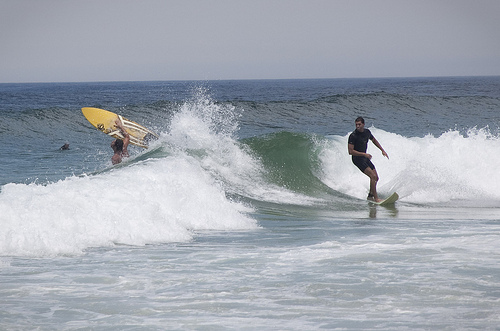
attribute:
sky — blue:
[0, 0, 499, 84]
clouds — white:
[1, 0, 499, 83]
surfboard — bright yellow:
[81, 103, 158, 149]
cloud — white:
[1, 24, 172, 70]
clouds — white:
[167, 17, 243, 44]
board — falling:
[78, 105, 163, 147]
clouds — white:
[167, 19, 269, 60]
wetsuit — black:
[350, 126, 374, 170]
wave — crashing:
[162, 80, 269, 232]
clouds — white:
[312, 21, 327, 49]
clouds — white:
[4, 4, 497, 76]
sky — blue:
[3, 4, 499, 76]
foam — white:
[2, 234, 498, 330]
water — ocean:
[0, 76, 499, 330]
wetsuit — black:
[346, 126, 401, 197]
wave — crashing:
[8, 77, 479, 262]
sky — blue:
[3, 3, 484, 103]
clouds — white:
[6, 9, 485, 77]